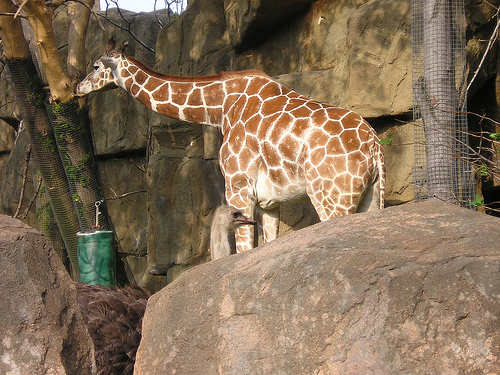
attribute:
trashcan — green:
[71, 212, 146, 312]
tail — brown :
[370, 142, 391, 212]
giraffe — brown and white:
[69, 34, 389, 266]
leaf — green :
[468, 193, 488, 210]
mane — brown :
[124, 55, 274, 82]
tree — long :
[355, 9, 481, 231]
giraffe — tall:
[70, 29, 389, 246]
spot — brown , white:
[134, 65, 149, 83]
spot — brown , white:
[169, 80, 194, 105]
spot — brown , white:
[270, 112, 292, 144]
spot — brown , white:
[340, 126, 358, 148]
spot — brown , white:
[325, 118, 342, 135]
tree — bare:
[92, 2, 196, 54]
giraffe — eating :
[71, 38, 439, 265]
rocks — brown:
[129, 8, 498, 373]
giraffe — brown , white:
[71, 50, 395, 246]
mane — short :
[114, 43, 274, 93]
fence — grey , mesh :
[394, 2, 497, 214]